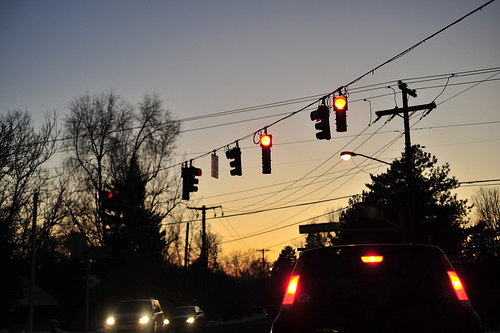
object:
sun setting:
[154, 157, 378, 253]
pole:
[114, 160, 131, 325]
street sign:
[296, 220, 366, 234]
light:
[331, 93, 353, 138]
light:
[257, 130, 273, 180]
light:
[307, 102, 329, 143]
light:
[99, 188, 113, 213]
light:
[183, 163, 203, 201]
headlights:
[100, 311, 198, 331]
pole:
[169, 176, 284, 273]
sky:
[0, 0, 495, 275]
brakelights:
[266, 231, 484, 316]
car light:
[137, 314, 149, 326]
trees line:
[4, 89, 498, 294]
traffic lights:
[165, 86, 367, 211]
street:
[58, 310, 498, 330]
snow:
[194, 299, 267, 331]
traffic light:
[225, 139, 245, 177]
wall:
[304, 83, 310, 101]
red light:
[99, 185, 122, 229]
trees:
[3, 94, 497, 304]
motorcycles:
[159, 312, 204, 328]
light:
[335, 146, 359, 164]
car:
[103, 297, 165, 332]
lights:
[98, 94, 351, 215]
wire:
[0, 41, 500, 200]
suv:
[266, 239, 492, 319]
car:
[158, 297, 218, 330]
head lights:
[160, 314, 194, 331]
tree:
[335, 141, 480, 239]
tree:
[63, 92, 188, 292]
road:
[210, 308, 270, 330]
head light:
[106, 315, 116, 330]